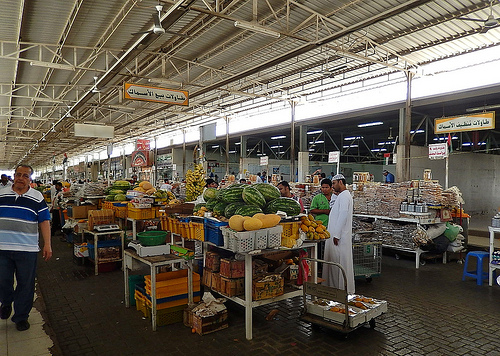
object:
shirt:
[0, 183, 52, 252]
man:
[1, 163, 54, 333]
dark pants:
[1, 249, 38, 324]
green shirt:
[309, 193, 331, 227]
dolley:
[300, 258, 389, 337]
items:
[306, 294, 387, 328]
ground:
[377, 70, 431, 97]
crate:
[143, 268, 200, 286]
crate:
[143, 281, 199, 290]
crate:
[142, 287, 202, 298]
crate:
[143, 299, 200, 326]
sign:
[122, 82, 189, 107]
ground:
[413, 105, 432, 122]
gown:
[323, 189, 357, 294]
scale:
[93, 224, 122, 233]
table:
[81, 226, 124, 275]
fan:
[131, 8, 194, 38]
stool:
[147, 203, 471, 234]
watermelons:
[202, 183, 302, 219]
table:
[203, 241, 319, 340]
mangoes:
[228, 213, 281, 231]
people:
[0, 163, 397, 332]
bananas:
[185, 164, 207, 202]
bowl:
[136, 230, 168, 246]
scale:
[128, 240, 171, 257]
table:
[123, 248, 195, 331]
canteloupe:
[228, 213, 282, 231]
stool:
[462, 250, 491, 286]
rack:
[193, 154, 202, 200]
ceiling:
[0, 0, 499, 171]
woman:
[309, 178, 337, 227]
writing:
[128, 89, 186, 102]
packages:
[302, 285, 387, 328]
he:
[321, 174, 357, 295]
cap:
[331, 174, 346, 182]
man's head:
[331, 174, 347, 193]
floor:
[33, 233, 499, 356]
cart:
[299, 257, 388, 338]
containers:
[128, 269, 201, 327]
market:
[0, 0, 499, 355]